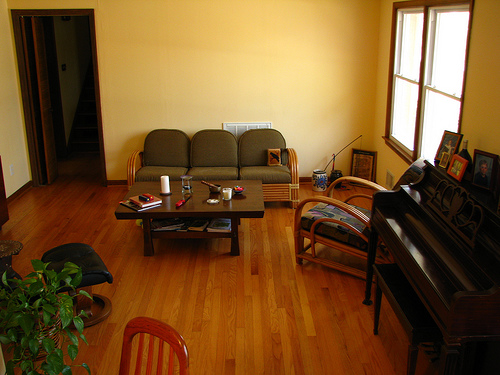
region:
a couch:
[153, 130, 267, 166]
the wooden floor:
[213, 293, 305, 365]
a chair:
[126, 316, 189, 361]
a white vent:
[227, 122, 259, 134]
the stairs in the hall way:
[68, 113, 99, 148]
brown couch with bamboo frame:
[123, 123, 303, 205]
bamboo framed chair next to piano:
[287, 169, 402, 279]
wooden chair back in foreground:
[111, 312, 188, 372]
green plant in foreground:
[6, 253, 95, 367]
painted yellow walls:
[4, 0, 499, 197]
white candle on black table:
[158, 170, 171, 197]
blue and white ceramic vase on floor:
[309, 165, 331, 192]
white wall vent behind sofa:
[223, 118, 274, 137]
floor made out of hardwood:
[195, 287, 298, 352]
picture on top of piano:
[471, 150, 498, 186]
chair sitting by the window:
[296, 171, 369, 285]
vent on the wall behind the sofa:
[221, 121, 271, 131]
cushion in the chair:
[318, 208, 333, 214]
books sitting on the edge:
[121, 187, 157, 212]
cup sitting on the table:
[218, 185, 236, 200]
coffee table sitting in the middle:
[121, 176, 266, 258]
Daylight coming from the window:
[435, 19, 465, 81]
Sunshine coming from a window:
[440, 19, 464, 79]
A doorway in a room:
[7, 5, 114, 192]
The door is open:
[30, 19, 72, 190]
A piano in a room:
[367, 168, 490, 366]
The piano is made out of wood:
[359, 168, 488, 360]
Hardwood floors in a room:
[201, 275, 310, 353]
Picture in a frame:
[470, 147, 495, 188]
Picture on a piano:
[473, 144, 495, 195]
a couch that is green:
[124, 105, 352, 245]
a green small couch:
[102, 103, 333, 193]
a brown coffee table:
[122, 162, 372, 309]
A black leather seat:
[36, 236, 123, 297]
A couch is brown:
[120, 120, 305, 212]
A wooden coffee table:
[110, 175, 270, 257]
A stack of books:
[110, 185, 166, 216]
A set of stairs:
[60, 45, 110, 165]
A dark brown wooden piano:
[355, 122, 495, 369]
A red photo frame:
[437, 145, 472, 182]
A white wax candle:
[155, 167, 175, 197]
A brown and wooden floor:
[0, 151, 437, 371]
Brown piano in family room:
[368, 156, 492, 371]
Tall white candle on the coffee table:
[154, 173, 174, 199]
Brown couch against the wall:
[125, 123, 307, 190]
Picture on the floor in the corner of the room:
[346, 140, 378, 192]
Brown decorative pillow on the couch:
[260, 143, 287, 171]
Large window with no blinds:
[378, 1, 475, 177]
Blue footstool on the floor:
[31, 238, 124, 334]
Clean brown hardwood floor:
[124, 254, 429, 372]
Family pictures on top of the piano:
[427, 123, 499, 195]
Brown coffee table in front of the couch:
[113, 174, 275, 262]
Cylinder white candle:
[159, 174, 170, 194]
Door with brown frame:
[8, 6, 110, 188]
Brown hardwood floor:
[2, 180, 432, 374]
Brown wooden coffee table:
[113, 178, 266, 259]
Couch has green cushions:
[125, 127, 300, 211]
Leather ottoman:
[33, 240, 114, 330]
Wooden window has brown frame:
[381, 2, 476, 165]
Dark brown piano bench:
[368, 260, 440, 373]